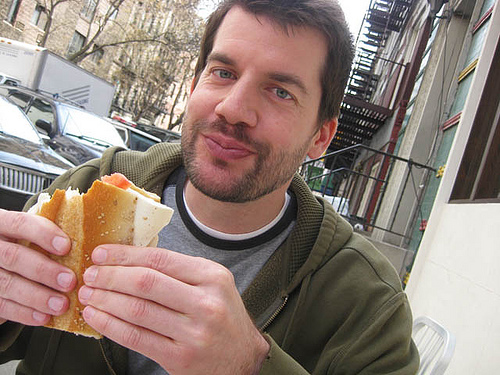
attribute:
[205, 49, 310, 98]
eye brows — dark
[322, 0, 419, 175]
fire escape — large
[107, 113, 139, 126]
red car — parked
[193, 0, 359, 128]
hair — dark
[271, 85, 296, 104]
eye — blue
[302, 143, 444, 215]
handrails — black, metal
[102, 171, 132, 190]
meat — pink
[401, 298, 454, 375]
chair — metal, silver